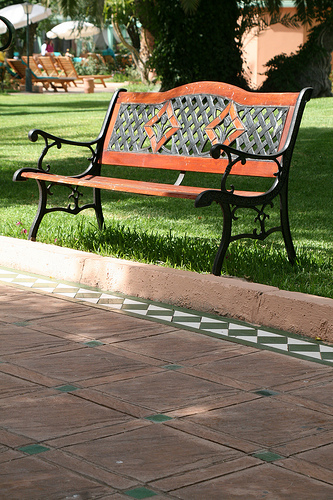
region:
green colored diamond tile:
[286, 341, 322, 353]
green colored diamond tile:
[256, 334, 287, 346]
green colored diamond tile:
[228, 328, 257, 337]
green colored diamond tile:
[198, 321, 228, 330]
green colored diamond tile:
[170, 316, 201, 322]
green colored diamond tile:
[148, 309, 173, 315]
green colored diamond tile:
[120, 303, 150, 309]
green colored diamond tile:
[74, 291, 102, 298]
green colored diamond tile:
[52, 286, 79, 293]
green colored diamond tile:
[11, 276, 36, 284]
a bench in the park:
[10, 78, 316, 275]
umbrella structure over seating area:
[42, 20, 102, 53]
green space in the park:
[5, 95, 323, 261]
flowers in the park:
[17, 216, 58, 244]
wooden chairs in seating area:
[4, 51, 130, 83]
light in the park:
[18, 3, 44, 90]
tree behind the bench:
[99, 5, 330, 104]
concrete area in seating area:
[74, 70, 120, 89]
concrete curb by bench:
[167, 262, 332, 330]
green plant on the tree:
[136, 6, 248, 84]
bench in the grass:
[22, 70, 308, 273]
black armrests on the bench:
[27, 124, 281, 187]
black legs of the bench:
[25, 182, 290, 264]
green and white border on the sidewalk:
[1, 261, 332, 369]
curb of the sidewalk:
[0, 231, 332, 338]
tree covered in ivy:
[119, 3, 330, 95]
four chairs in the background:
[6, 46, 119, 97]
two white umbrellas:
[1, 5, 97, 42]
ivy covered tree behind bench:
[107, 9, 250, 82]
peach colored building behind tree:
[134, 6, 324, 102]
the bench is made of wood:
[87, 67, 285, 237]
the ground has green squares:
[26, 419, 232, 495]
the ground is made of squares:
[44, 395, 238, 490]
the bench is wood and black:
[27, 101, 165, 183]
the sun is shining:
[5, 82, 221, 247]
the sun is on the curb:
[17, 207, 134, 303]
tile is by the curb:
[136, 292, 238, 350]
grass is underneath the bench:
[100, 178, 192, 258]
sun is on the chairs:
[26, 10, 109, 100]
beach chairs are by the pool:
[13, 43, 134, 91]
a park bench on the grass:
[3, 66, 331, 287]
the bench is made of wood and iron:
[0, 73, 329, 292]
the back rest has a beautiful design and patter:
[108, 82, 298, 179]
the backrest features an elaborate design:
[93, 69, 322, 192]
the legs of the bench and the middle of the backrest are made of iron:
[12, 78, 316, 311]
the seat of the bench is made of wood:
[18, 163, 264, 221]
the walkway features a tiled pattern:
[1, 245, 326, 498]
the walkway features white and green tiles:
[2, 262, 327, 498]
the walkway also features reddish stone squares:
[1, 270, 330, 498]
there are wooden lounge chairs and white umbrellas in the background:
[0, 0, 111, 84]